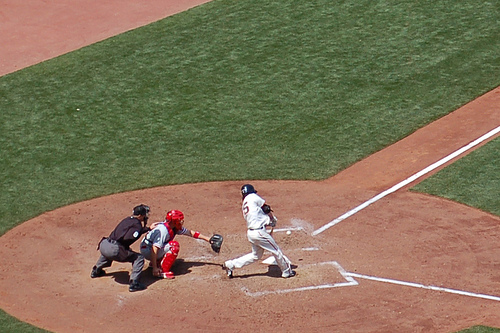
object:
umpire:
[85, 199, 160, 300]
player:
[135, 203, 228, 286]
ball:
[284, 226, 292, 237]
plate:
[262, 250, 293, 268]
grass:
[1, 0, 499, 224]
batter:
[216, 178, 297, 281]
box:
[214, 220, 363, 300]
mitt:
[208, 232, 228, 255]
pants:
[221, 228, 296, 279]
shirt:
[102, 214, 149, 246]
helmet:
[163, 208, 185, 238]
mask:
[132, 202, 152, 225]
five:
[241, 201, 252, 216]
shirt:
[243, 192, 269, 231]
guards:
[161, 240, 180, 274]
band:
[192, 230, 200, 241]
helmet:
[238, 181, 260, 197]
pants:
[90, 236, 144, 284]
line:
[309, 120, 499, 236]